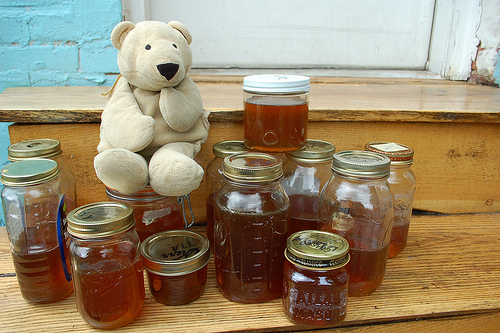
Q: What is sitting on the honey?
A: A bear.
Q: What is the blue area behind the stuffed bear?
A: A wall.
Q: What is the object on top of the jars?
A: A stuffed bear.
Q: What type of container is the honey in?
A: A jar.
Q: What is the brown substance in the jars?
A: Honey.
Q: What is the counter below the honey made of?
A: Wood.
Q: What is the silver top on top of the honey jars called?
A: A lid.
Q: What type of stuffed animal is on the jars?
A: A bear.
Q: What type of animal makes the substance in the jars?
A: Bees.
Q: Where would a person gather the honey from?
A: A beehive.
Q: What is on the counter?
A: Toy bear and bottles.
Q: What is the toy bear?
A: Black and white.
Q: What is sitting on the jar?
A: Stuffed bear.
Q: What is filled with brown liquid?
A: Mason jars.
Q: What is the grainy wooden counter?
A: Brown.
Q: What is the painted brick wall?
A: Blue.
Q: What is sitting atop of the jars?
A: White capped jar.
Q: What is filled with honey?
A: Pint jar.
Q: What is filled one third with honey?
A: Quart jar.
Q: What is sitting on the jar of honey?
A: Beige teddy bear.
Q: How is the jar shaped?
A: Rounded.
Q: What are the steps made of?
A: Wood.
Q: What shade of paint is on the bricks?
A: Light blue.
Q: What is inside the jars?
A: Honey.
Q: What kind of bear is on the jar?
A: A teddy bear.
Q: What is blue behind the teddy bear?
A: The walls.